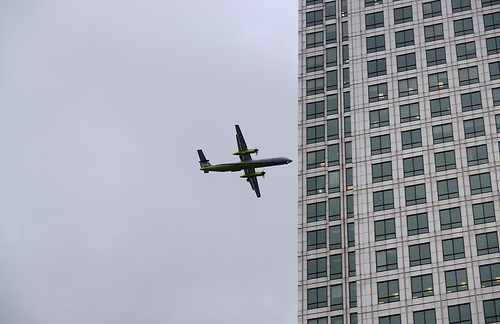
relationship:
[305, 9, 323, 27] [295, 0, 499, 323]
window of building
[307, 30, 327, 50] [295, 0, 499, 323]
window of building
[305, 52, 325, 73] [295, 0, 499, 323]
window of building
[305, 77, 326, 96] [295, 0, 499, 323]
window of building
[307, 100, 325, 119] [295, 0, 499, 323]
window of building